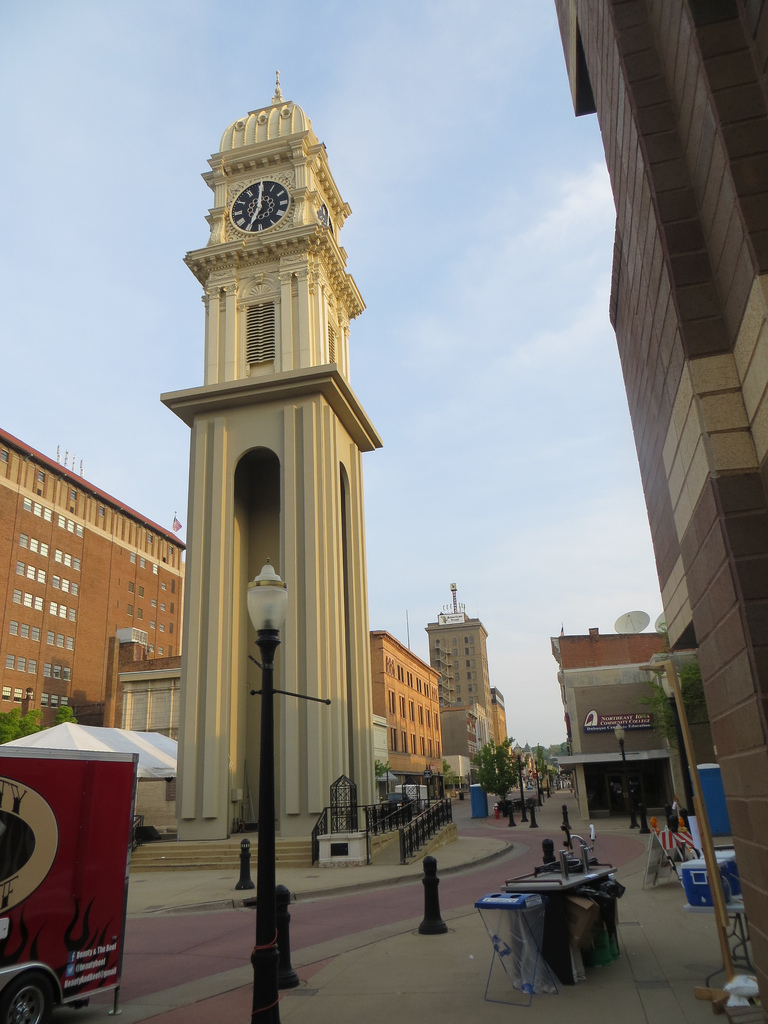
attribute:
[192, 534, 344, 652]
light — off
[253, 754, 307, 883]
pole — black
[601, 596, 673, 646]
dish — satellite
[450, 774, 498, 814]
porta pot — blue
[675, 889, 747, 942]
table — white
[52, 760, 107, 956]
trailer — red, parked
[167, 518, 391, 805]
tower — clock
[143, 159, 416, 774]
tower — clock, tan, black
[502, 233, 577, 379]
clouds — white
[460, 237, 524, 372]
clouds — thin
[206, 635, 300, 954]
pole — black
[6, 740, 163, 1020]
red truck — red , parked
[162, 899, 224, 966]
red brick — red 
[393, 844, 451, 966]
black pylon — black 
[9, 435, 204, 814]
building — red brick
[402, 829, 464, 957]
metal pole — metal 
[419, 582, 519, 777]
building — tan , tall , thin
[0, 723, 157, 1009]
red trailer — red , parked 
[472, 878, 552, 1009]
recycling can — Blue 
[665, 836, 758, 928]
cooler — Blue , white 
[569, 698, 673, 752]
sign — Red, blue, white 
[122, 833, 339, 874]
stone steps — stone 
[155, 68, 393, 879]
clocktower — Tall , beige 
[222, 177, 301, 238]
clock face — dark , circular 